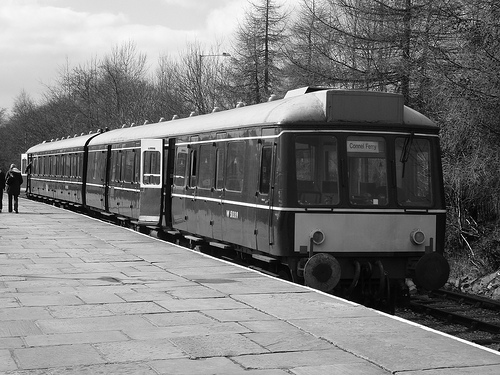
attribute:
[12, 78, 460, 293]
train — long, stopped, grey, white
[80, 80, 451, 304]
cars — first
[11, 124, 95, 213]
cars — second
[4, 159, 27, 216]
person — waiting, loading, standing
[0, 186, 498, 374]
sidewalk — cement, grey, stone, tiles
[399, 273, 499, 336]
track — metal, iron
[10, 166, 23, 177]
hat — white, beige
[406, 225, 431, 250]
headlight — small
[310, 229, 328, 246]
headlight — small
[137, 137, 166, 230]
door — open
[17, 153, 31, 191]
door — back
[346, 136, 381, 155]
sign — white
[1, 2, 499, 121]
sky — grey, overcast, cloudy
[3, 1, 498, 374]
photograph — black, white, outdoor, daytime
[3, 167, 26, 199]
coat — black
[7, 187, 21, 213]
pants — black